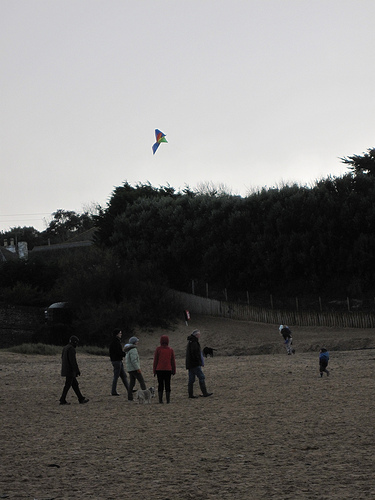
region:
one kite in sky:
[135, 107, 177, 191]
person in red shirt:
[145, 322, 185, 409]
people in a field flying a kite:
[53, 310, 241, 412]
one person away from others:
[272, 300, 305, 361]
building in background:
[6, 212, 143, 285]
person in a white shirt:
[126, 335, 146, 381]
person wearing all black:
[50, 322, 101, 423]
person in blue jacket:
[304, 336, 341, 385]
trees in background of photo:
[82, 185, 373, 275]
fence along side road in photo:
[129, 256, 341, 343]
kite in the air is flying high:
[150, 121, 174, 159]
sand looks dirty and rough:
[28, 430, 172, 492]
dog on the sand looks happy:
[136, 379, 160, 408]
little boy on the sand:
[301, 340, 345, 382]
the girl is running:
[274, 316, 300, 374]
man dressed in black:
[39, 327, 87, 421]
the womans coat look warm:
[118, 341, 144, 372]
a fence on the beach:
[177, 280, 366, 335]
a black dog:
[202, 345, 219, 357]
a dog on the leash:
[132, 382, 158, 405]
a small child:
[312, 343, 331, 380]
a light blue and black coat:
[312, 346, 335, 381]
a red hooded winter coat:
[151, 334, 178, 380]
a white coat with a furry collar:
[122, 341, 145, 373]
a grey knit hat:
[126, 330, 138, 349]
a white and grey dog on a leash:
[134, 386, 158, 409]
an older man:
[182, 324, 218, 410]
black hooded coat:
[184, 334, 208, 382]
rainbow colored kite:
[145, 118, 183, 168]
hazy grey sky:
[3, 2, 370, 222]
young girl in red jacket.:
[145, 333, 175, 404]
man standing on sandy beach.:
[179, 322, 210, 409]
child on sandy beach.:
[310, 342, 336, 383]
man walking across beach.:
[46, 322, 87, 423]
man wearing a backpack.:
[266, 313, 301, 367]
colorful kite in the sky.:
[138, 129, 177, 161]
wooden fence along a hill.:
[149, 267, 373, 334]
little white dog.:
[131, 383, 162, 406]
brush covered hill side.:
[109, 149, 373, 207]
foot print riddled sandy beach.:
[0, 345, 372, 498]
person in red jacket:
[151, 333, 177, 405]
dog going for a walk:
[133, 381, 157, 405]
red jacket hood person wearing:
[154, 332, 173, 351]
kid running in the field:
[315, 345, 333, 380]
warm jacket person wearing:
[121, 341, 142, 374]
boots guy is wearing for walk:
[185, 375, 213, 400]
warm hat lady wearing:
[127, 334, 140, 346]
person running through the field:
[277, 320, 298, 356]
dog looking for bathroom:
[201, 341, 219, 359]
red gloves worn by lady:
[134, 365, 145, 376]